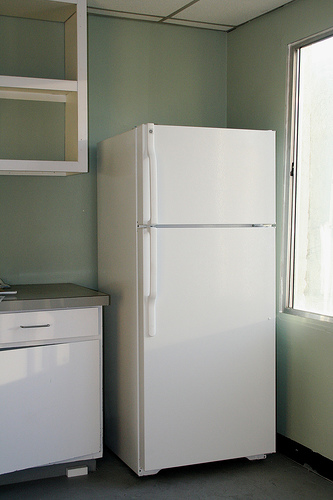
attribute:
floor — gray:
[171, 464, 292, 494]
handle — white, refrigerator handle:
[143, 225, 161, 339]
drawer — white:
[6, 302, 122, 351]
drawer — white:
[0, 306, 99, 344]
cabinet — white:
[2, 309, 105, 475]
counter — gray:
[1, 265, 106, 313]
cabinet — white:
[18, 282, 76, 371]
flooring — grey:
[2, 466, 332, 495]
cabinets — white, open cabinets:
[0, 0, 98, 186]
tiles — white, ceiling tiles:
[211, 467, 291, 498]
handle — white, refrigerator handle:
[143, 122, 158, 226]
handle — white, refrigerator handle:
[145, 226, 158, 335]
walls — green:
[139, 27, 269, 117]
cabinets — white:
[0, 0, 91, 179]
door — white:
[138, 229, 196, 292]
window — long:
[279, 27, 331, 320]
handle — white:
[143, 145, 163, 215]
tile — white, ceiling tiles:
[87, 1, 329, 42]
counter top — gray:
[26, 271, 90, 306]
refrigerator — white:
[93, 120, 284, 474]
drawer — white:
[0, 304, 104, 346]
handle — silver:
[19, 323, 49, 328]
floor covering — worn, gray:
[0, 452, 333, 498]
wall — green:
[97, 18, 251, 135]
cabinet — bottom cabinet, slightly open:
[1, 337, 105, 477]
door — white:
[139, 123, 280, 225]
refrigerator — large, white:
[71, 107, 291, 475]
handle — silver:
[10, 317, 54, 341]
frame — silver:
[268, 33, 328, 327]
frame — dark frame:
[98, 0, 279, 68]